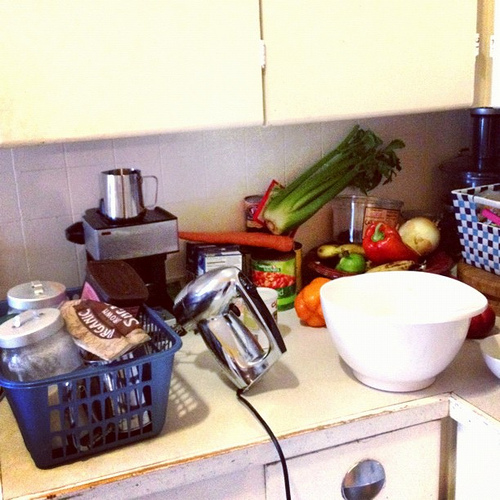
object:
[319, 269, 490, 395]
bowl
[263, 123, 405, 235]
vegetable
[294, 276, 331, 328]
pepper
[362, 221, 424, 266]
pepper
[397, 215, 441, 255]
onion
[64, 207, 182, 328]
coffee maker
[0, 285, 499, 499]
counter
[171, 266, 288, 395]
mixer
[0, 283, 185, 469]
basket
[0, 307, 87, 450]
jar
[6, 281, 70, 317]
jar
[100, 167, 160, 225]
coffee mug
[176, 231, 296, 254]
carrot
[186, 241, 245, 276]
box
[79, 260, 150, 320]
container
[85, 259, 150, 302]
lid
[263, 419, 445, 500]
drawer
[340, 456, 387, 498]
handle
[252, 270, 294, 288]
tomatoes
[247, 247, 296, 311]
can